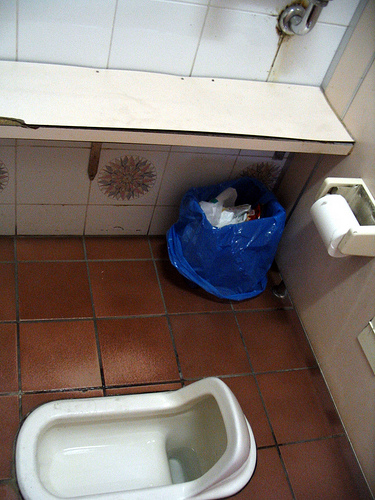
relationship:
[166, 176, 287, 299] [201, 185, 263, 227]
bag in trash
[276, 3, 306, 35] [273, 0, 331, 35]
rust around pipe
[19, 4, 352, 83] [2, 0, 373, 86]
tile on wall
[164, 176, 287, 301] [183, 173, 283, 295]
bag in trashcan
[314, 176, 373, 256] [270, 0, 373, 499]
holder attached to wall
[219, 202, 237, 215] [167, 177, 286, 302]
trash in garbage can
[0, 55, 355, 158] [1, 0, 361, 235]
bench attached to wall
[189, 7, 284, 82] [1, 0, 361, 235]
white tile on wall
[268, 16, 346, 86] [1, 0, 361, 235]
white tile on wall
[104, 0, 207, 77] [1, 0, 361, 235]
white tile on wall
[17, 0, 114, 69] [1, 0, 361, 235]
tile on wall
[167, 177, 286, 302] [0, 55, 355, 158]
garbage can under bench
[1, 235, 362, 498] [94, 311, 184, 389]
floor made of tile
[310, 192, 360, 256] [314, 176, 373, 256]
roll on holder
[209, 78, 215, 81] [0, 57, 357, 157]
nail securing counter top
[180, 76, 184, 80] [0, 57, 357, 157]
nail securing counter top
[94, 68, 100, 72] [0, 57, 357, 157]
nail securing counter top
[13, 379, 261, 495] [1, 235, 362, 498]
toilet mounted on floor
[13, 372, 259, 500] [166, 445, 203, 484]
toilet containing water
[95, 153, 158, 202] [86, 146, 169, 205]
design printed on tile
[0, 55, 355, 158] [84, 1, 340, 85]
bench hanging on wall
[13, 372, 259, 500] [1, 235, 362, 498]
toilet mounted on floor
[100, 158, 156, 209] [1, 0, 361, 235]
tile adorning wall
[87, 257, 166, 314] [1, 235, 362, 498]
tile covering floor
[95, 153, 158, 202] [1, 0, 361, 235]
design adorning wall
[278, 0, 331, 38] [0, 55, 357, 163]
pipe mounted above bench